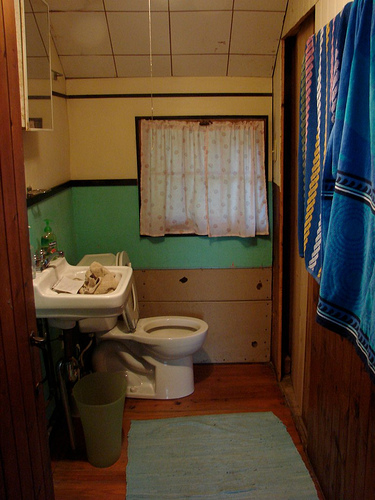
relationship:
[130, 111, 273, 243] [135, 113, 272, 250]
curtain on window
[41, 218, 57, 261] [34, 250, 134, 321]
soap on sink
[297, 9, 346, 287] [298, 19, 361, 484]
towel on door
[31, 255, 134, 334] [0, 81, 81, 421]
sink on wall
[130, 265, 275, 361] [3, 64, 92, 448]
cabinet on wall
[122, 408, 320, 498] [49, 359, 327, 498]
floor rug on floor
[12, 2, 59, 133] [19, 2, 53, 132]
cabinet with mirror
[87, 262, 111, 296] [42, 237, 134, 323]
towel in sink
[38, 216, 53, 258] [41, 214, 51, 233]
bottle with lid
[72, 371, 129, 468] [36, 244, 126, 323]
garbage can next to sink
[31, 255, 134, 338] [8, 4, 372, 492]
sink in bathroom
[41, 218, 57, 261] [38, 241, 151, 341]
soap sitting on sink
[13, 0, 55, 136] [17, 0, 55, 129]
cabinet with mirror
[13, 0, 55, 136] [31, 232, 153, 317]
cabinet over sink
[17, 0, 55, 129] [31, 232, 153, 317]
mirror over sink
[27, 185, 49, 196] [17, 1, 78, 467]
dish mounted on wall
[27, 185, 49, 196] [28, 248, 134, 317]
dish over sink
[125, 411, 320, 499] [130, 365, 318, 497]
floor rug on floor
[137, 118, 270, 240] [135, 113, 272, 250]
curtain on window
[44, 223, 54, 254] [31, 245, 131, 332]
soap on sink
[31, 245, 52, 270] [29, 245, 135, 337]
faucet on sink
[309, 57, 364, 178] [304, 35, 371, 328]
towel on shower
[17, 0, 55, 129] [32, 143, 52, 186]
mirror on wall